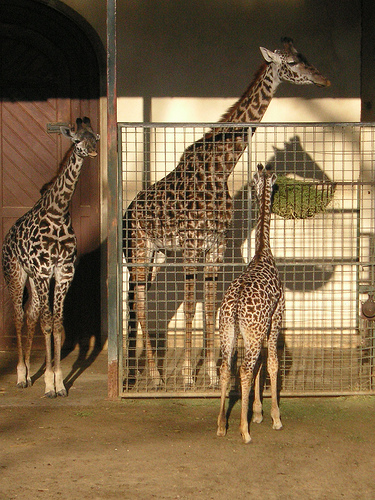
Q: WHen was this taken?
A: Daytime.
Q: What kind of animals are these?
A: Giraffes.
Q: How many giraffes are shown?
A: 3.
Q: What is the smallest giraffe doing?
A: Eating.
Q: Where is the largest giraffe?
A: Behind the fence.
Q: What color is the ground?
A: Brown.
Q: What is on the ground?
A: Dirt.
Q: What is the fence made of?
A: Metal.